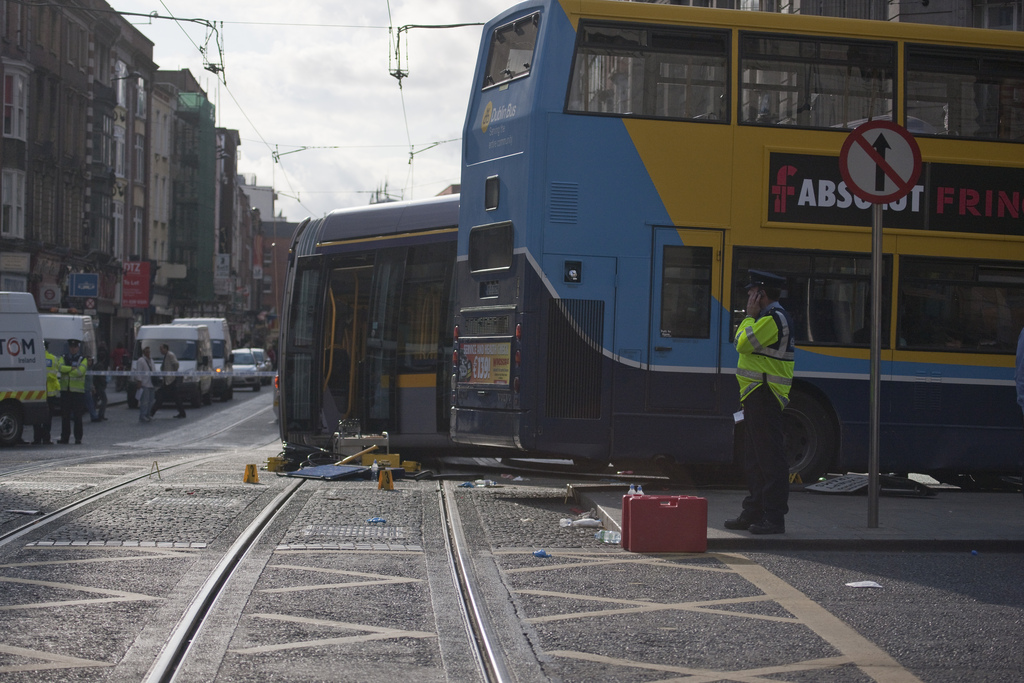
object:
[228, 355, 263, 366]
windshield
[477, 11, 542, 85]
window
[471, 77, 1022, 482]
bus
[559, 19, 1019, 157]
window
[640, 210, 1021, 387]
window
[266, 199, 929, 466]
bus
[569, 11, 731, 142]
window bus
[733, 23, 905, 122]
window bus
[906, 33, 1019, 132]
window bus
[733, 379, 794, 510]
pants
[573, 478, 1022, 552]
sidewalk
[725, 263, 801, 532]
policeman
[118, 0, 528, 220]
white clouds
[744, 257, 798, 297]
hat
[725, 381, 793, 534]
man`s legs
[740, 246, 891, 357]
window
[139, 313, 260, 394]
vehicles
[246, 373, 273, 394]
tire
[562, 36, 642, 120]
window bus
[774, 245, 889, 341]
window bus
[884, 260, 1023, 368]
window bus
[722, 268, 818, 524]
policeman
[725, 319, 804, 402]
yellow coat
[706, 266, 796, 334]
head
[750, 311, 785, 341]
shoulders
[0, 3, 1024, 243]
sky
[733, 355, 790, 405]
torso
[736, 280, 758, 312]
facial area